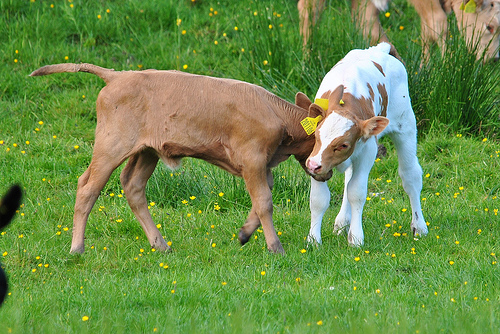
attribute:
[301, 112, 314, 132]
tag — yellow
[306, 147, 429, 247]
legs — white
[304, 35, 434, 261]
cow — white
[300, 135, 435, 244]
legs — white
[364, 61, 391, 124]
spots — brown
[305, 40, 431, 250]
calf — white, brown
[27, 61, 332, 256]
calf — brown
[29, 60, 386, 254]
calf — brown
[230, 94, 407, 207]
cow eating — brown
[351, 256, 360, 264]
flower — tiny, yellow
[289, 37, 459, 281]
cow — baby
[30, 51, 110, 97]
tail — brown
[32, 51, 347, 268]
calf — white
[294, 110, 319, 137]
tag — yellow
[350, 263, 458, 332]
grass — green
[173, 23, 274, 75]
grass — tall, green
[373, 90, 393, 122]
markings — brown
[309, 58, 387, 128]
markings — brown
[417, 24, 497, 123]
grass blades — tall, green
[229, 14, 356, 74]
grass blades — tall, green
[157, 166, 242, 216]
grass blades — tall, green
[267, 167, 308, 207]
grass blades — tall, green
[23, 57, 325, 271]
cow — brown, baby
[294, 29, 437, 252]
cow — brown, white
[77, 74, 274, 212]
body — brown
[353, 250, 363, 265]
dandelions — yellow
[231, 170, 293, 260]
legs — brown